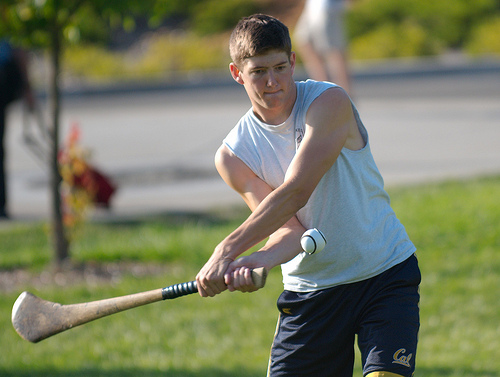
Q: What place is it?
A: It is a field.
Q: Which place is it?
A: It is a field.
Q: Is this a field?
A: Yes, it is a field.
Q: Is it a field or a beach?
A: It is a field.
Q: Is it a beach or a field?
A: It is a field.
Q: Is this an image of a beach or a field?
A: It is showing a field.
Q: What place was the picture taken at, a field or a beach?
A: It was taken at a field.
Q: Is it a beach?
A: No, it is a field.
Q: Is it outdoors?
A: Yes, it is outdoors.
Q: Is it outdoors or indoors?
A: It is outdoors.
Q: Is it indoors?
A: No, it is outdoors.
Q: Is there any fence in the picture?
A: No, there are no fences.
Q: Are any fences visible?
A: No, there are no fences.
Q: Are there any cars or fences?
A: No, there are no fences or cars.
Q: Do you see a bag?
A: No, there are no bags.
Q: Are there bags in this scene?
A: No, there are no bags.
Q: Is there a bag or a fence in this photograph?
A: No, there are no bags or fences.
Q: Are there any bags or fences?
A: No, there are no bags or fences.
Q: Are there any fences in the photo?
A: No, there are no fences.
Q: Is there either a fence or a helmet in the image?
A: No, there are no fences or helmets.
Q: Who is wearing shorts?
A: The boy is wearing shorts.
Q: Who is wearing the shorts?
A: The boy is wearing shorts.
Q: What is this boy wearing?
A: The boy is wearing shorts.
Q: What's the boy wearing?
A: The boy is wearing shorts.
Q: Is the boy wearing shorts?
A: Yes, the boy is wearing shorts.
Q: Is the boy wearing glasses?
A: No, the boy is wearing shorts.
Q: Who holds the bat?
A: The boy holds the bat.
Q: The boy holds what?
A: The boy holds the bat.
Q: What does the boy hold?
A: The boy holds the bat.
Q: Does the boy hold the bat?
A: Yes, the boy holds the bat.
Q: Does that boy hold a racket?
A: No, the boy holds the bat.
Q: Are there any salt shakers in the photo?
A: No, there are no salt shakers.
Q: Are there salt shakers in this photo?
A: No, there are no salt shakers.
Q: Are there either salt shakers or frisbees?
A: No, there are no salt shakers or frisbees.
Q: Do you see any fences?
A: No, there are no fences.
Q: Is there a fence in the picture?
A: No, there are no fences.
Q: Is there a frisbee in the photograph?
A: No, there are no frisbees.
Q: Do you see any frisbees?
A: No, there are no frisbees.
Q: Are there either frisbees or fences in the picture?
A: No, there are no frisbees or fences.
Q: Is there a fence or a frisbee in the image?
A: No, there are no frisbees or fences.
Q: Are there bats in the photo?
A: Yes, there is a bat.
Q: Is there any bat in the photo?
A: Yes, there is a bat.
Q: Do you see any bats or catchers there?
A: Yes, there is a bat.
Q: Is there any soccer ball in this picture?
A: No, there are no soccer balls.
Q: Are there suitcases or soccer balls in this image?
A: No, there are no soccer balls or suitcases.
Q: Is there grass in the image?
A: Yes, there is grass.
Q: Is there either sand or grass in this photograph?
A: Yes, there is grass.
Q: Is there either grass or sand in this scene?
A: Yes, there is grass.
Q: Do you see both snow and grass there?
A: No, there is grass but no snow.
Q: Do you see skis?
A: No, there are no skis.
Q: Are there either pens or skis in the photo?
A: No, there are no skis or pens.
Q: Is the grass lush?
A: Yes, the grass is lush.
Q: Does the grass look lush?
A: Yes, the grass is lush.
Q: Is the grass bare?
A: No, the grass is lush.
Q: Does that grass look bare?
A: No, the grass is lush.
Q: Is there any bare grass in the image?
A: No, there is grass but it is lush.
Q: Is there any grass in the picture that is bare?
A: No, there is grass but it is lush.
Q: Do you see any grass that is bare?
A: No, there is grass but it is lush.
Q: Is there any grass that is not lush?
A: No, there is grass but it is lush.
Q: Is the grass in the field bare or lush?
A: The grass is lush.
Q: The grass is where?
A: The grass is in the field.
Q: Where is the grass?
A: The grass is in the field.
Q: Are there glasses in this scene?
A: No, there are no glasses.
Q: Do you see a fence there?
A: No, there are no fences.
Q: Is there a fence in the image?
A: No, there are no fences.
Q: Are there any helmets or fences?
A: No, there are no fences or helmets.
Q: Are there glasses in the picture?
A: No, there are no glasses.